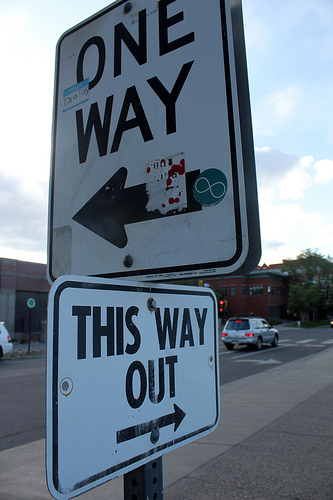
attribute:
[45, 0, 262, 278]
sign — black, white, one way sign, pointed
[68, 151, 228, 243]
arrow — pointing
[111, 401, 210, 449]
arrow — pointing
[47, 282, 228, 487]
sign — white, bottom sign, pointing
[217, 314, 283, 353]
car — stopped, parked, white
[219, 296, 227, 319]
traffic signal — red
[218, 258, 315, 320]
buidling — red, brick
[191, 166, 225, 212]
sticker — white, green, blue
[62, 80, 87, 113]
sticker — blue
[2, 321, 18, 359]
van — grey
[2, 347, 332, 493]
sidewalk — grey, stone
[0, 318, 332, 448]
road — black, asphalt, paved, tarmac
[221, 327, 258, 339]
taillights — red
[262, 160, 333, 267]
clouds — white, puffy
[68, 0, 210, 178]
lettering — black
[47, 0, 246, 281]
street sign — white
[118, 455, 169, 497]
pole — metal, grey, black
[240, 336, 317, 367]
lines — white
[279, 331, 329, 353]
stripes — white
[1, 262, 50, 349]
wall — stone, brown, red, brick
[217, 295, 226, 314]
stoplight — red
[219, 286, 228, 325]
post — black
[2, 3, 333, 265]
skies — blue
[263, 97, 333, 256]
skies — cloudy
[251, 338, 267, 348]
wheel — rear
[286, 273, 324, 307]
leaves — green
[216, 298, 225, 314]
lights — red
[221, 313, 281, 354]
station wagon — silver, stopped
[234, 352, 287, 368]
arrow — painted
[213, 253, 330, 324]
building — brick, red